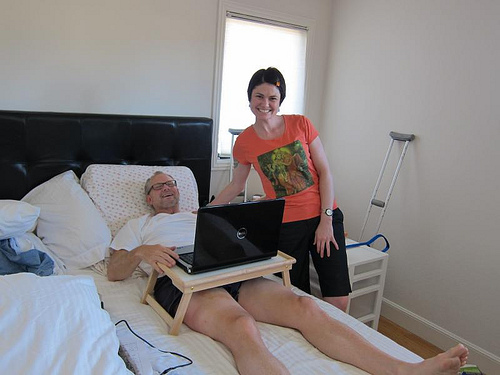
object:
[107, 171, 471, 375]
man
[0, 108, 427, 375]
bed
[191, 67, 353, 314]
woman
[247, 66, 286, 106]
short hair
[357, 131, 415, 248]
crutch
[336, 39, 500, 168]
wall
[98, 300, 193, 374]
cord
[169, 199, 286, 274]
laptop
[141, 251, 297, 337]
tray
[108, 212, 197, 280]
tee shirt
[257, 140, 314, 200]
design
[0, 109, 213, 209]
bedframe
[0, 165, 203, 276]
pillow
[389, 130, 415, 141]
gray pads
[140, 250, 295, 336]
bed desk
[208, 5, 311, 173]
window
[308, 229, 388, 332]
nightstand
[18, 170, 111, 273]
pillows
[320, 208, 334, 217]
watch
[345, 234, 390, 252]
spectacle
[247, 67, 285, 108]
brown hair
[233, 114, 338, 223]
orange shirt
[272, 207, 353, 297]
shorts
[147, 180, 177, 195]
glasses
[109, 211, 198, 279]
white shirt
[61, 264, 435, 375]
sheet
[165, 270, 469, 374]
legs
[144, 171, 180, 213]
head